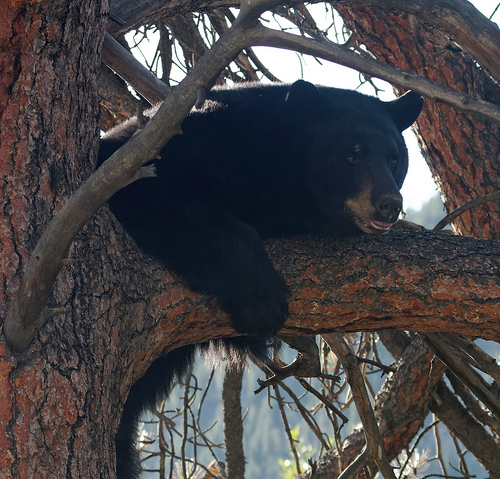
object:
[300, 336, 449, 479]
branch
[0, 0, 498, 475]
tree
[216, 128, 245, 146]
fur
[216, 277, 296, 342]
bearpaw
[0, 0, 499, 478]
background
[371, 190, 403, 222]
nose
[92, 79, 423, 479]
bear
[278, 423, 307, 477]
leaves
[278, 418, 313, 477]
plant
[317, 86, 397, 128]
top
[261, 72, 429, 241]
head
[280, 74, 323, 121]
ear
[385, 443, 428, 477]
flowers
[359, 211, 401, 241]
mouth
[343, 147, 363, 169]
eye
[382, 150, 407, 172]
eye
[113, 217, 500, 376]
branch